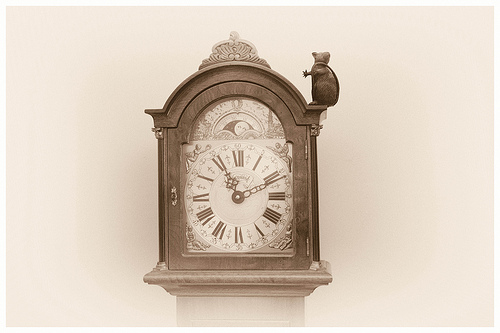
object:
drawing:
[185, 223, 211, 252]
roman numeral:
[234, 226, 243, 244]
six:
[234, 226, 243, 243]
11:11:
[206, 142, 294, 214]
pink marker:
[142, 30, 340, 297]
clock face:
[184, 142, 294, 252]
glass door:
[181, 95, 297, 252]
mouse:
[302, 51, 340, 106]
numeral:
[197, 174, 215, 182]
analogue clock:
[181, 99, 292, 253]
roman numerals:
[212, 221, 228, 240]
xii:
[229, 147, 246, 169]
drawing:
[193, 97, 286, 141]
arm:
[242, 183, 268, 198]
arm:
[223, 170, 241, 194]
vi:
[234, 225, 244, 242]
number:
[252, 155, 263, 171]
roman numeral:
[231, 146, 248, 168]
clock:
[143, 29, 340, 299]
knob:
[170, 184, 179, 208]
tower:
[144, 30, 339, 297]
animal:
[302, 51, 341, 106]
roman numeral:
[252, 154, 264, 172]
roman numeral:
[264, 170, 279, 182]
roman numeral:
[268, 190, 286, 200]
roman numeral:
[262, 207, 282, 224]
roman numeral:
[253, 223, 265, 238]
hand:
[232, 175, 286, 204]